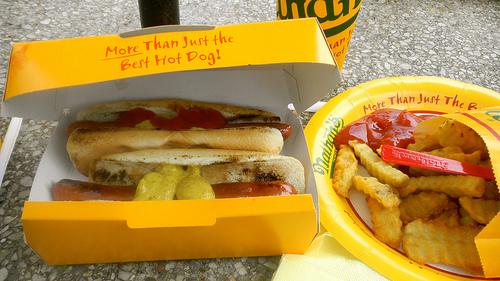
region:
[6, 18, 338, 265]
hot dogs in open carton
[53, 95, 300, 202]
two hot dogs in box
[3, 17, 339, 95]
top of yellow carton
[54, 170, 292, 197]
mustard on cooked hot dog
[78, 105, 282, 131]
ketchup and mustard on hot dog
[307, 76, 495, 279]
frech fries on plate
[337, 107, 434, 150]
ketchup on paper plate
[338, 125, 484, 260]
crinkle cut french fries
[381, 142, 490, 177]
handle of red plastic utensil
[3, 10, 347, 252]
two hot dogs in paper container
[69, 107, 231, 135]
ketchup on hot dog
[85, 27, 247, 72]
phrase on hot dog container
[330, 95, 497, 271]
crinkle fries on plate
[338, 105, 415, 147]
ketchup on plate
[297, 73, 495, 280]
yellow paper plate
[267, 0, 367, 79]
paper drinking cup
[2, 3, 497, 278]
granite table top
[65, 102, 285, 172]
hot dog bun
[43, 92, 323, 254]
Two hotdogs are inside the box.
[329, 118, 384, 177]
The ketsup is next to the fries.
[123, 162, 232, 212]
Mustard is on top of the hotdog.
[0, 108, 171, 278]
The box is on top of the table.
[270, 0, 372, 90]
The soda cup is on top of the table.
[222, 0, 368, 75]
The soda cup is next to the hotdog box.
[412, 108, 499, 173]
The fries are inside of the bag.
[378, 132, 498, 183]
The utensil is inside of the bag.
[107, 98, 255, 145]
The ketsup is on top of the hotdog.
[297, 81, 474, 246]
food on the plate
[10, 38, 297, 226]
food in the box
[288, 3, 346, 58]
drink in the cup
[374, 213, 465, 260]
fries on the plate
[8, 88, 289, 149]
hot dog in the box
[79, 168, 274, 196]
hot dog in the box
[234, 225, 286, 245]
the box is yellow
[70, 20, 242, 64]
writing on the box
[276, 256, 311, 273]
napkin on the table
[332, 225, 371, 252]
the plate is yellow